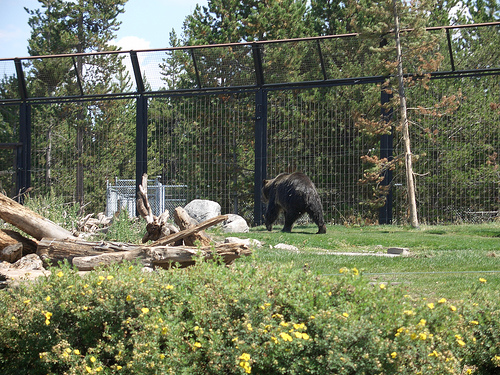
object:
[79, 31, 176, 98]
cloud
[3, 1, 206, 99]
sky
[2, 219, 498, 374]
grass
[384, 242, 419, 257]
small step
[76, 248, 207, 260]
logs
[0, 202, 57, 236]
logs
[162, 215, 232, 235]
logs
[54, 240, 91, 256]
logs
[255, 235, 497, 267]
ground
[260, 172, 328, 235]
bear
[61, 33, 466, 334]
zoo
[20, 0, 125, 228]
trees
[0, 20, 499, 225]
fence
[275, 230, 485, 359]
field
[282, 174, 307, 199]
fur